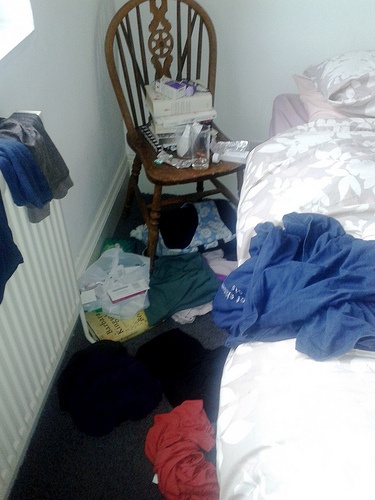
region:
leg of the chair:
[146, 188, 164, 267]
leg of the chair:
[127, 161, 138, 216]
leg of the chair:
[196, 184, 211, 211]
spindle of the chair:
[115, 29, 143, 127]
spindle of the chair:
[176, 6, 186, 76]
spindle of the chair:
[134, 8, 153, 91]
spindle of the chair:
[128, 21, 139, 74]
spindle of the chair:
[185, 13, 194, 73]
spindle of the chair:
[119, 28, 131, 47]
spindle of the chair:
[195, 19, 207, 75]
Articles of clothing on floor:
[121, 214, 231, 324]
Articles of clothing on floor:
[62, 267, 220, 497]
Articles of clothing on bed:
[218, 216, 365, 369]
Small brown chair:
[85, 5, 256, 247]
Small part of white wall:
[51, 248, 83, 287]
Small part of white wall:
[58, 287, 81, 319]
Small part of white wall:
[40, 223, 88, 262]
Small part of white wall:
[5, 206, 45, 255]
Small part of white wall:
[5, 326, 83, 421]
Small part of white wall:
[0, 409, 36, 463]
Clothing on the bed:
[202, 197, 373, 375]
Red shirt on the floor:
[148, 390, 223, 498]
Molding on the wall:
[17, 331, 35, 371]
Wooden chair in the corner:
[90, 29, 312, 257]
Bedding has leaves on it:
[271, 118, 374, 193]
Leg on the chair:
[137, 194, 176, 255]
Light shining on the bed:
[243, 360, 363, 445]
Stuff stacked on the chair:
[147, 68, 253, 200]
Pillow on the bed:
[298, 54, 366, 126]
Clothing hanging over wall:
[6, 111, 99, 214]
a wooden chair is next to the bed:
[103, 0, 245, 255]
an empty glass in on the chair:
[189, 123, 210, 170]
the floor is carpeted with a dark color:
[15, 194, 238, 499]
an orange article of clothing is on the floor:
[142, 398, 217, 498]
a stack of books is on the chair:
[142, 83, 215, 154]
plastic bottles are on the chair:
[211, 137, 251, 165]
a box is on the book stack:
[154, 69, 189, 98]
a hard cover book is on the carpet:
[85, 301, 150, 346]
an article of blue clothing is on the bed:
[217, 211, 374, 361]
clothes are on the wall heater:
[2, 108, 82, 488]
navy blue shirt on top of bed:
[237, 256, 346, 335]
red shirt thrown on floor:
[139, 384, 205, 493]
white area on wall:
[58, 66, 104, 129]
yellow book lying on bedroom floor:
[80, 299, 182, 348]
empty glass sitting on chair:
[189, 127, 222, 174]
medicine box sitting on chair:
[150, 73, 186, 106]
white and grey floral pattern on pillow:
[300, 45, 372, 105]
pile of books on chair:
[142, 80, 218, 143]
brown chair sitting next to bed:
[116, 7, 240, 73]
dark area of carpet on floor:
[84, 400, 142, 476]